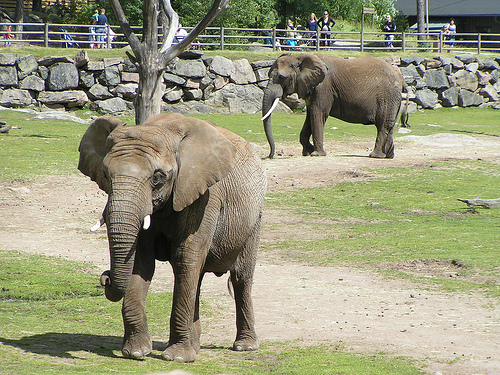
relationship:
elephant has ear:
[79, 114, 267, 363] [174, 114, 235, 213]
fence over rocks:
[0, 21, 499, 56] [2, 47, 136, 118]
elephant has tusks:
[79, 114, 267, 363] [87, 216, 155, 235]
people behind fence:
[262, 9, 338, 51] [0, 21, 499, 56]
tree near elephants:
[105, 1, 226, 126] [77, 51, 410, 363]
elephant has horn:
[79, 114, 267, 363] [143, 213, 153, 230]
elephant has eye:
[79, 114, 267, 363] [101, 170, 109, 183]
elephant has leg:
[79, 114, 267, 363] [119, 245, 157, 360]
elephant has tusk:
[79, 114, 267, 363] [90, 214, 109, 233]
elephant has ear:
[79, 114, 267, 363] [75, 117, 119, 191]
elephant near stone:
[79, 114, 267, 363] [205, 54, 232, 81]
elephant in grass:
[79, 114, 267, 363] [2, 248, 430, 374]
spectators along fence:
[85, 6, 116, 47] [0, 21, 499, 56]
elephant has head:
[79, 114, 267, 363] [77, 116, 233, 302]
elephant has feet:
[79, 114, 267, 363] [112, 331, 262, 364]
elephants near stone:
[77, 51, 410, 363] [205, 54, 232, 81]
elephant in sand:
[79, 114, 267, 363] [6, 235, 499, 369]